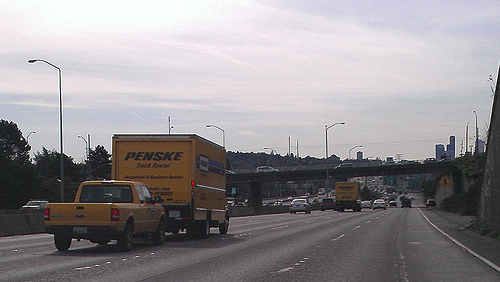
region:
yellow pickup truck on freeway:
[70, 181, 164, 241]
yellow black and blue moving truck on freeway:
[131, 136, 222, 181]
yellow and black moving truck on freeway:
[338, 182, 360, 204]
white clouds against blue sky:
[7, 7, 203, 51]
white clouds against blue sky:
[122, 7, 280, 108]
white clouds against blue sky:
[272, 5, 482, 112]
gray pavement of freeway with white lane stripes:
[253, 216, 330, 264]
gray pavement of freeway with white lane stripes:
[310, 220, 427, 269]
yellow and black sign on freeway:
[440, 174, 450, 187]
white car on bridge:
[256, 163, 281, 172]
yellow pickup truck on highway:
[56, 179, 164, 254]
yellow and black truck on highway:
[121, 139, 227, 181]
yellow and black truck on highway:
[329, 179, 367, 216]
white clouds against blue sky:
[84, 20, 230, 114]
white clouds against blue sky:
[244, 50, 307, 138]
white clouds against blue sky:
[362, 50, 419, 150]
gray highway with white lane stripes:
[261, 219, 431, 270]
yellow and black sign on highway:
[436, 173, 451, 188]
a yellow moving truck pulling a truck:
[41, 127, 238, 258]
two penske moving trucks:
[109, 113, 376, 240]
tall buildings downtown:
[344, 133, 461, 193]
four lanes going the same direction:
[9, 197, 499, 279]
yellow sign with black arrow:
[432, 167, 457, 204]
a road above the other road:
[218, 150, 449, 182]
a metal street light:
[319, 112, 351, 202]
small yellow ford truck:
[39, 177, 170, 253]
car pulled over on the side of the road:
[420, 187, 450, 215]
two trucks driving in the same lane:
[68, 127, 379, 239]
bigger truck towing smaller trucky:
[20, 123, 245, 249]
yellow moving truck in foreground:
[110, 120, 240, 230]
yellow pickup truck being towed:
[35, 175, 165, 245]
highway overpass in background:
[235, 152, 498, 182]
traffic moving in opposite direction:
[233, 185, 304, 207]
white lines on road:
[252, 215, 421, 272]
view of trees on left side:
[6, 126, 108, 198]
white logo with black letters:
[195, 152, 215, 172]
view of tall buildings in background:
[422, 129, 490, 161]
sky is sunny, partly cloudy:
[0, 4, 499, 152]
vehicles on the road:
[52, 112, 480, 280]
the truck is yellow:
[46, 167, 178, 254]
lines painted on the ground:
[261, 195, 378, 272]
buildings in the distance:
[337, 120, 487, 161]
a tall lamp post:
[11, 43, 101, 253]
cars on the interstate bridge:
[234, 145, 469, 185]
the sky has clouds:
[218, 32, 403, 134]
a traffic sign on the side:
[434, 148, 469, 219]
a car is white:
[368, 189, 393, 219]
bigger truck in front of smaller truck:
[74, 103, 231, 255]